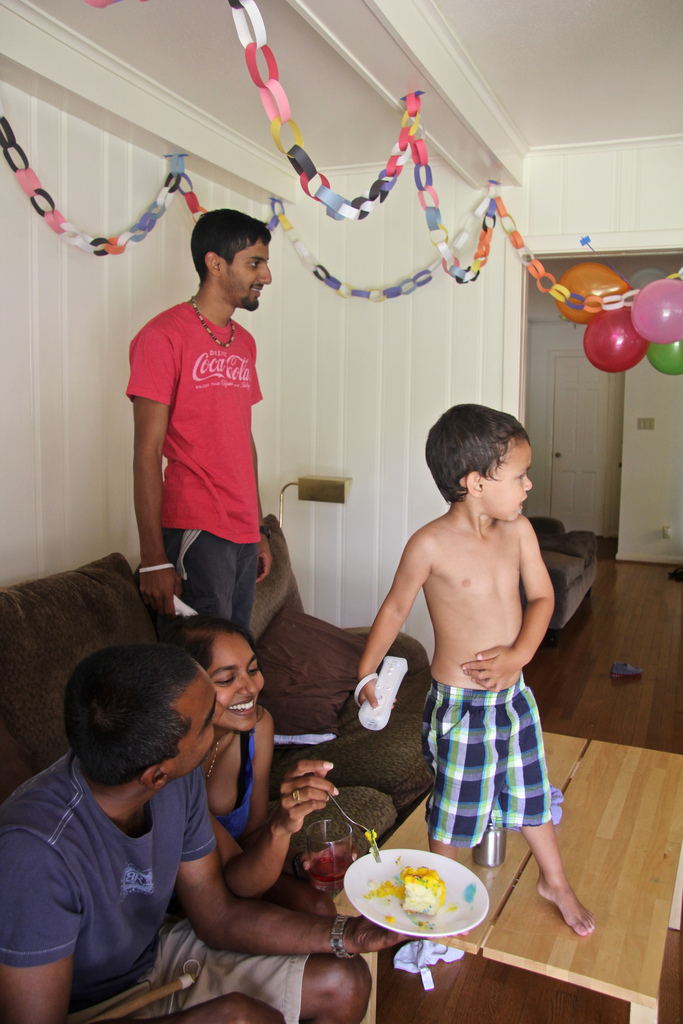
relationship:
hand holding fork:
[271, 754, 341, 832] [310, 753, 382, 859]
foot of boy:
[536, 877, 597, 935] [355, 402, 597, 936]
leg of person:
[496, 720, 597, 936] [354, 404, 595, 934]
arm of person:
[355, 526, 432, 706] [354, 404, 595, 934]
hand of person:
[459, 642, 522, 692] [354, 404, 595, 934]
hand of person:
[351, 662, 379, 707] [354, 404, 595, 934]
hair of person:
[423, 402, 533, 504] [354, 404, 595, 934]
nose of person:
[519, 478, 535, 488] [354, 404, 595, 934]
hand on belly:
[459, 642, 522, 692] [427, 601, 522, 686]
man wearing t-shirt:
[125, 204, 271, 642] [123, 300, 261, 544]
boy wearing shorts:
[355, 402, 597, 936] [422, 672, 553, 846]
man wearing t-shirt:
[2, 636, 413, 1021] [1, 750, 218, 1008]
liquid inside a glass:
[312, 848, 349, 880] [303, 813, 351, 909]